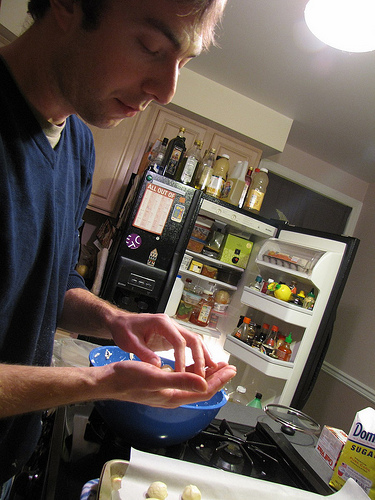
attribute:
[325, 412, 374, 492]
bag — sugar, white, yellow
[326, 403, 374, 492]
sugar — domino, domino brand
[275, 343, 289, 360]
sauce — red, sriracha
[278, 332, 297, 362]
bottle — green, large, clear, juice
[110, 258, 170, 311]
ice dispencer — black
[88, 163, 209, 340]
door — refrigerator's, refrigerator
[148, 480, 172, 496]
ball — white, dough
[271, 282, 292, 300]
ball — yellow, lemon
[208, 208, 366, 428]
door — refrigerator's, open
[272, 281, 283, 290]
top — green, white, lying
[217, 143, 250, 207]
bottle — oil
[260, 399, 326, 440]
pot top — clear, glass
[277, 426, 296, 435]
knob — black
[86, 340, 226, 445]
bowl — metal, blue, plastic, big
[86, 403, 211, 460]
burner — stove's, black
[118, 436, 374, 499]
paper — white, parchment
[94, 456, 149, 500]
pan — tin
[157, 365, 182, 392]
dough — white, rolled, cookie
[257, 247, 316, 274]
carton — eggs, grey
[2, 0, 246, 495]
man — making, dressed, standing, cooking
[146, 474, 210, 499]
cookies — sugar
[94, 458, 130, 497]
tray — cooking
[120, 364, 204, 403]
mixture — cookie dough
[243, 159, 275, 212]
bottle — juice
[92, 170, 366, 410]
refrigerator — black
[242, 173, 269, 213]
juice — grapefruit, lemon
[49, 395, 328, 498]
stove — black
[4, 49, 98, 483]
t-shirt — vee neck, navy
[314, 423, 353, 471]
box — butter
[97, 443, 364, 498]
cookie sheet — lined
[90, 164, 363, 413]
fridge — black, open, full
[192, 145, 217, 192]
bottle — liquor, wine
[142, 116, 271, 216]
bottles — liquor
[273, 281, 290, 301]
container — yellow, plastic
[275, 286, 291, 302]
juice — lemon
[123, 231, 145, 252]
magnet — purple, white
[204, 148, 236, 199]
container — juice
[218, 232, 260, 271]
box — wine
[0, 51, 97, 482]
shirt — blue